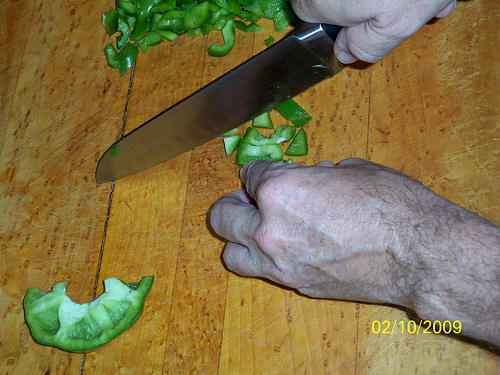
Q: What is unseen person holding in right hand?
A: Knife.